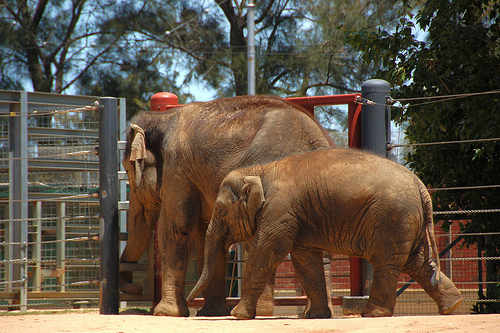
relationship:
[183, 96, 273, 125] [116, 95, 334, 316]
hair on elephant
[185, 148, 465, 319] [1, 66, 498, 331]
elephant in pen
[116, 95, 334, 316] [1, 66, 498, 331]
elephant in pen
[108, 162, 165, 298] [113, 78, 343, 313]
trunk of elephant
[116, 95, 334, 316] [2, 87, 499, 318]
elephant in an enclosure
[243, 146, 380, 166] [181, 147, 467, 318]
hair on elephant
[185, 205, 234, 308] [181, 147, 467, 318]
trunk on elephant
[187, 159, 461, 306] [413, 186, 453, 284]
elephant has tail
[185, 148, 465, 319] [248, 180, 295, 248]
elephant has ear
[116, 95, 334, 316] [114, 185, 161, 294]
elephant has trunk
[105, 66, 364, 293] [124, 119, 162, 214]
elephant has ear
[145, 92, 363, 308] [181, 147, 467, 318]
gate behind elephant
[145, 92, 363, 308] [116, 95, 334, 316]
gate behind elephant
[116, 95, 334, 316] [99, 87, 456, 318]
elephant walking with elephant